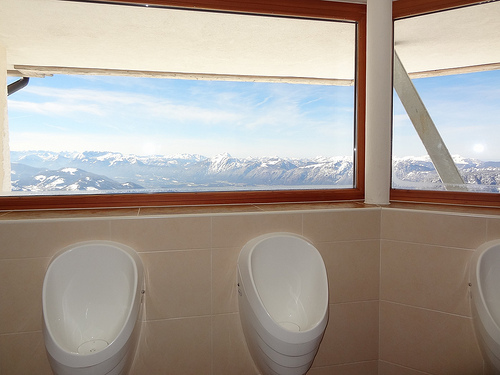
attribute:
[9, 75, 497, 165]
sky — blue, white, cloudy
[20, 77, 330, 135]
clouds — white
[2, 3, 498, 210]
frame — brown, wooden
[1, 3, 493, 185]
window — glass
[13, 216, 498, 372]
wall — brown, tiled, beige, tan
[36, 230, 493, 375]
urinals — white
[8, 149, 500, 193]
mountains — large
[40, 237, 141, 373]
urinal — white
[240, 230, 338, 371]
urinal — white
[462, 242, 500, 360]
urinal — white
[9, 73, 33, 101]
support — gray, metal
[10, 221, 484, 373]
grout — white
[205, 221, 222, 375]
crack — white